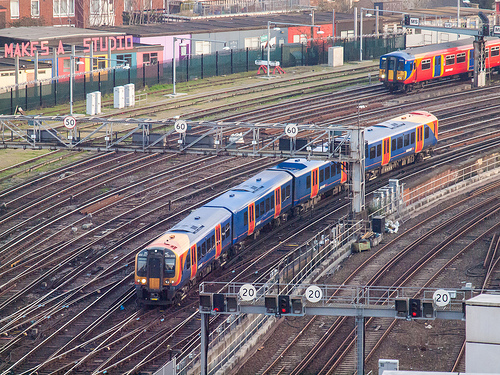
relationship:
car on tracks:
[132, 109, 439, 309] [35, 98, 498, 368]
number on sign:
[173, 119, 190, 135] [171, 117, 190, 137]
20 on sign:
[239, 288, 259, 299] [235, 278, 259, 308]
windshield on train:
[133, 255, 149, 276] [133, 101, 437, 304]